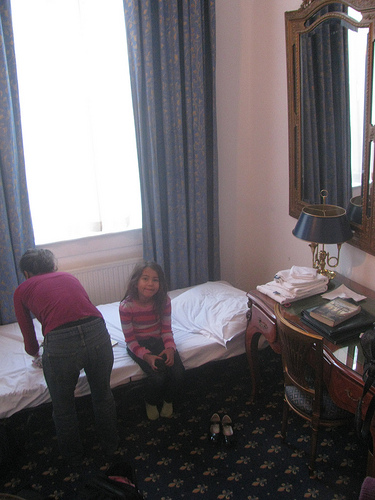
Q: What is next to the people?
A: Wall.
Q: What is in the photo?
A: Curtains.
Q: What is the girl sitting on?
A: Bed sheets.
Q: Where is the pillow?
A: On the bed.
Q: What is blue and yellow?
A: Curtains.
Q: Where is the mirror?
A: Wall.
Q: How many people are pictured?
A: 2.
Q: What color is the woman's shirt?
A: Pink.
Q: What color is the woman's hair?
A: Brown.